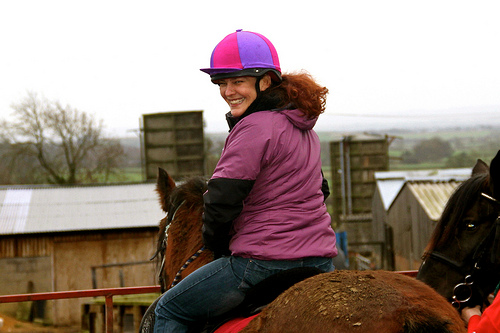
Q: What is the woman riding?
A: A horse.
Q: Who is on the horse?
A: A woman.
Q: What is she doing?
A: Smiling.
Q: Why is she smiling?
A: She's happy.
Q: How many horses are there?
A: Two.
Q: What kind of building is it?
A: A barn.